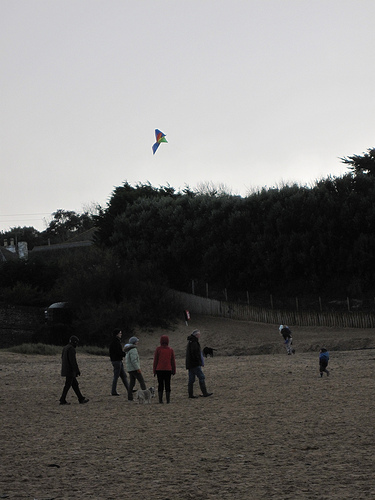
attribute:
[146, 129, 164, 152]
kite — flying, colored, colorful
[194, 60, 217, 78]
sky — hazy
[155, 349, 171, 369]
shirt — red, white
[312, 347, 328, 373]
person — standing, running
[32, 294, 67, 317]
building — background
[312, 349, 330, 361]
jacket — blue, warm, red, white, hooded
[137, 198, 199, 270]
trees — background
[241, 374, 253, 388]
sand — dirty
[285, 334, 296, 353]
dog — black, white, little, walking, looking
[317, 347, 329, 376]
boy — small, running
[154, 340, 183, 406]
girl — running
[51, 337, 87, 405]
man — older, standing, walking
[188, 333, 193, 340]
hat — knit, warm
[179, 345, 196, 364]
coat — black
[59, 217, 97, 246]
hill — covered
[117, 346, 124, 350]
gloves — red